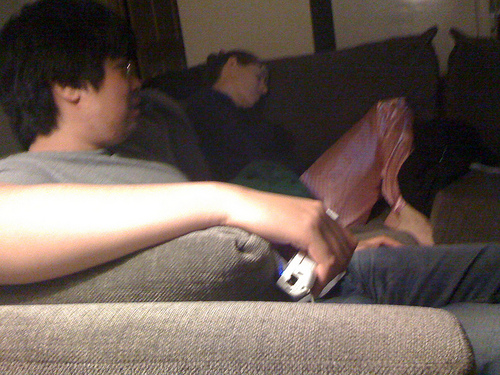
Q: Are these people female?
A: No, they are both male and female.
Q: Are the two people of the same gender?
A: No, they are both male and female.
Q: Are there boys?
A: No, there are no boys.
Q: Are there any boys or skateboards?
A: No, there are no boys or skateboards.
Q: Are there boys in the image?
A: No, there are no boys.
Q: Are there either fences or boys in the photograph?
A: No, there are no boys or fences.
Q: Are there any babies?
A: No, there are no babies.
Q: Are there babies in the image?
A: No, there are no babies.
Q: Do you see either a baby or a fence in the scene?
A: No, there are no babies or fences.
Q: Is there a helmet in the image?
A: No, there are no helmets.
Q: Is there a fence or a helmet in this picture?
A: No, there are no helmets or fences.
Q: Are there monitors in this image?
A: No, there are no monitors.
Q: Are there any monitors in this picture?
A: No, there are no monitors.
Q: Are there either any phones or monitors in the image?
A: No, there are no monitors or phones.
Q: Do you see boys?
A: No, there are no boys.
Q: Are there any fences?
A: No, there are no fences.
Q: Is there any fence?
A: No, there are no fences.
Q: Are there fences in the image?
A: No, there are no fences.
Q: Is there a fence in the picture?
A: No, there are no fences.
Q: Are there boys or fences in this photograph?
A: No, there are no fences or boys.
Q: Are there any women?
A: Yes, there is a woman.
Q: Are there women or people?
A: Yes, there is a woman.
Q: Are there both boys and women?
A: No, there is a woman but no boys.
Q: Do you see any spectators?
A: No, there are no spectators.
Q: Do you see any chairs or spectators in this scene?
A: No, there are no spectators or chairs.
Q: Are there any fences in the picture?
A: No, there are no fences.